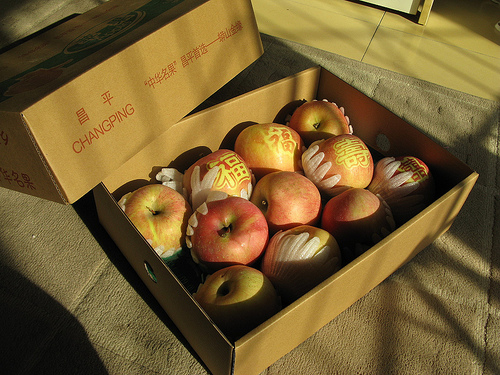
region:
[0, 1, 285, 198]
Cardboard lid to box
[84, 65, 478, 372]
Cardboard box with fruit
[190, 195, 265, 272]
Red apple in box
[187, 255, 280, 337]
Yellow apple in box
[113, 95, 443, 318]
Eleven apples in box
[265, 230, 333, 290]
Soft white protective cover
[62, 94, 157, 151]
Red words on box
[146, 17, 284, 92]
Red Asian writing on box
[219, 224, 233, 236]
Brown stem on apple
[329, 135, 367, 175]
Yellow lettering on apple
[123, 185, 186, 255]
a red and green apple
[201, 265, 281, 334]
a red and green apple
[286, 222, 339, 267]
a red and green apple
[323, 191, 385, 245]
a red and green apple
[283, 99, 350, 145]
a red and green apple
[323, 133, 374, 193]
a red and green printed apple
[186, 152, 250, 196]
a red and green printed apple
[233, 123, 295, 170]
a red and green printed apple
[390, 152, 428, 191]
a red and green printed apple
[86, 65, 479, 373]
a large cardboard box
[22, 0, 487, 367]
box of apples in cardboard box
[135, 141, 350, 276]
white finger-like protection on apples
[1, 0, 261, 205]
lid resting on corner of box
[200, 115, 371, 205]
Asian writing on some apples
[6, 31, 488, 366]
light brown rug under box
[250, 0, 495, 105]
yellow tiles covering floor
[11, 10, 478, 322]
shadows falling over floor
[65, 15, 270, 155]
red English and Asian writing on box side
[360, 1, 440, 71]
bottom corner of furniture reflected on floor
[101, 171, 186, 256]
red and yellow apple in corner of box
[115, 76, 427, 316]
The apples in the box.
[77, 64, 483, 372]
The box holding the apples.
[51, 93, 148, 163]
The word Changping on the box.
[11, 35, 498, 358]
The gray rug the box is on.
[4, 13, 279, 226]
The lid of the box.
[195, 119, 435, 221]
The four apples with a yellow design on them.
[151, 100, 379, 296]
The white encasing around the apples.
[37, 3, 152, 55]
The green design on the lid of the box.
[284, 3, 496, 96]
The yellow tiles on the floor.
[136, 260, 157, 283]
The hole on the left side of the box.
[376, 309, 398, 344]
part of a sahde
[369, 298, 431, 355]
part of a shade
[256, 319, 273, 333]
edge of a box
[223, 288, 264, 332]
part of an apple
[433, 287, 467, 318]
part of a shade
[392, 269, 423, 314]
part of a floor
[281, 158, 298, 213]
part of a fruit